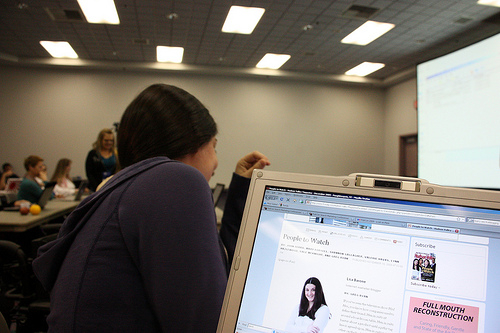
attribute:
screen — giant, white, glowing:
[397, 41, 497, 198]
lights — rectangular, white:
[345, 58, 386, 78]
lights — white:
[341, 20, 388, 47]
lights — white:
[258, 52, 288, 71]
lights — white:
[219, 5, 261, 36]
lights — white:
[156, 43, 185, 63]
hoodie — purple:
[30, 155, 230, 331]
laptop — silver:
[213, 166, 498, 331]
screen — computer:
[232, 185, 498, 332]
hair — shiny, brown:
[115, 82, 220, 185]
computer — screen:
[216, 165, 498, 332]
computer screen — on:
[215, 167, 498, 332]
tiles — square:
[11, 3, 498, 96]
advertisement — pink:
[404, 295, 481, 330]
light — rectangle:
[220, 3, 269, 40]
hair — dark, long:
[97, 132, 186, 181]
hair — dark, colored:
[121, 88, 182, 124]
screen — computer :
[198, 160, 473, 331]